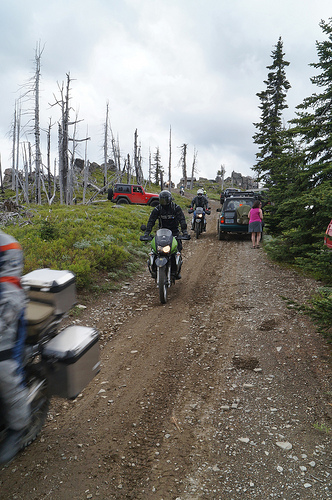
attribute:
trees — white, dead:
[18, 74, 179, 221]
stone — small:
[275, 440, 293, 451]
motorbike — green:
[143, 231, 187, 303]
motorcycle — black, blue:
[185, 203, 212, 237]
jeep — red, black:
[102, 173, 162, 209]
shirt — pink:
[248, 207, 261, 221]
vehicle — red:
[110, 181, 155, 210]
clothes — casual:
[252, 203, 263, 235]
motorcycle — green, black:
[138, 222, 191, 304]